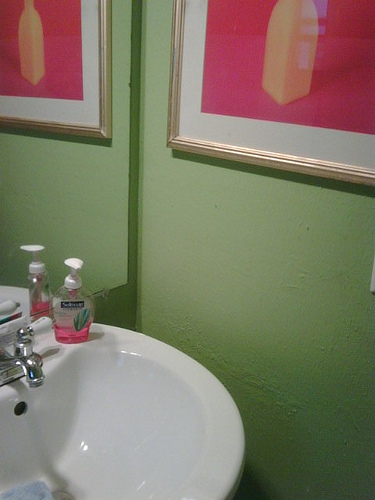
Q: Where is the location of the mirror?
A: On the wall.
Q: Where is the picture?
A: On the wall.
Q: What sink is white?
A: Bathroom.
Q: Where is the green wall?
A: Bathroom.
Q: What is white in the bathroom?
A: The sink.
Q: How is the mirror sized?
A: Large.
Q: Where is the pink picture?
A: Bathroom wall.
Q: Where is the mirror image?
A: In the mirror.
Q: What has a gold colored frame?
A: The picture.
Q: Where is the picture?
A: Wall.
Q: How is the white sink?
A: Small.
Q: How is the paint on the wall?
A: Green.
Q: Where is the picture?
A: Wall.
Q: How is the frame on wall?
A: Bronze.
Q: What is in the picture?
A: A bathroom corner.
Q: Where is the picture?
A: Right wall.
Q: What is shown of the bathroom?
A: The sink.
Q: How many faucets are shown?
A: One.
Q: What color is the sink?
A: White.